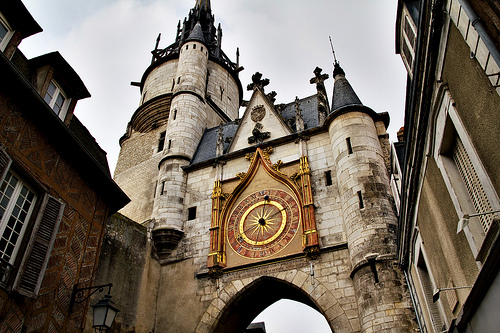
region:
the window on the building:
[0, 156, 36, 293]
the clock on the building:
[196, 135, 326, 260]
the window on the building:
[43, 72, 76, 121]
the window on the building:
[0, 17, 16, 54]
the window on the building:
[432, 101, 499, 254]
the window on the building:
[411, 237, 448, 332]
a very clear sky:
[17, 2, 407, 178]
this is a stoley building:
[0, 0, 497, 331]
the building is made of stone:
[1, 0, 498, 331]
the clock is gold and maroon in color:
[206, 132, 318, 277]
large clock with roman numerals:
[207, 146, 322, 266]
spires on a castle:
[130, 0, 360, 105]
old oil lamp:
[71, 280, 116, 330]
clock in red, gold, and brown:
[207, 144, 321, 273]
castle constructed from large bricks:
[111, 0, 421, 330]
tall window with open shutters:
[0, 145, 62, 302]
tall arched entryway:
[193, 275, 353, 331]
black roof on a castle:
[186, 65, 328, 162]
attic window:
[38, 49, 90, 131]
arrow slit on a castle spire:
[345, 136, 353, 157]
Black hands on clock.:
[241, 206, 286, 244]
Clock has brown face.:
[246, 202, 312, 278]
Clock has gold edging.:
[205, 157, 326, 308]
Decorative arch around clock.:
[211, 152, 323, 279]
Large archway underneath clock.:
[173, 281, 392, 331]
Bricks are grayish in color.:
[323, 161, 379, 331]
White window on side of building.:
[6, 190, 25, 262]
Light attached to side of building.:
[68, 265, 133, 327]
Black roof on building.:
[295, 102, 332, 117]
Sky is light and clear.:
[96, 98, 110, 126]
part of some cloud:
[243, 2, 295, 39]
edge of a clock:
[238, 237, 275, 272]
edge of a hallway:
[263, 272, 303, 313]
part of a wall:
[168, 262, 203, 293]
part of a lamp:
[95, 303, 117, 323]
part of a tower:
[366, 280, 398, 322]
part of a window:
[0, 228, 32, 285]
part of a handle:
[66, 268, 108, 298]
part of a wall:
[439, 223, 467, 268]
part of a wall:
[62, 170, 95, 209]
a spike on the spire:
[321, 22, 345, 64]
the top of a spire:
[327, 64, 372, 114]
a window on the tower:
[341, 132, 359, 159]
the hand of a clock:
[258, 193, 272, 218]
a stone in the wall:
[231, 275, 246, 291]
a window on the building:
[35, 70, 71, 121]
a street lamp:
[88, 291, 121, 331]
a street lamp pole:
[66, 275, 119, 315]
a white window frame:
[426, 84, 499, 264]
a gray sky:
[16, 0, 413, 181]